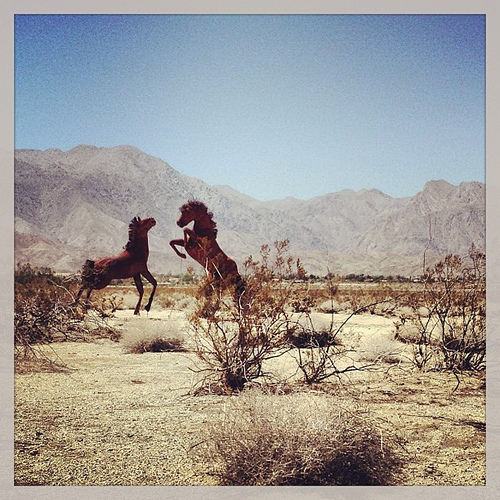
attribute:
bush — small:
[182, 382, 399, 495]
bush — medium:
[185, 243, 335, 398]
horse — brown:
[155, 198, 260, 314]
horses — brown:
[76, 214, 160, 314]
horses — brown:
[175, 197, 251, 311]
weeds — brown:
[299, 327, 479, 472]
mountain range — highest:
[66, 142, 494, 264]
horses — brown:
[87, 204, 249, 322]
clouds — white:
[116, 53, 193, 103]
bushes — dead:
[181, 243, 390, 405]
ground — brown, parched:
[18, 272, 483, 482]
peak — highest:
[73, 142, 140, 154]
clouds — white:
[168, 55, 241, 112]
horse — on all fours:
[55, 201, 176, 338]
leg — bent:
[171, 239, 192, 262]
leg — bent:
[179, 225, 196, 242]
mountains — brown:
[16, 140, 486, 276]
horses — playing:
[74, 199, 249, 317]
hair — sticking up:
[120, 216, 137, 253]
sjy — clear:
[66, 40, 498, 163]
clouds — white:
[376, 97, 439, 142]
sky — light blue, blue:
[16, 19, 480, 201]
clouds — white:
[208, 134, 294, 172]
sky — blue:
[177, 22, 377, 201]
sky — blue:
[126, 20, 436, 146]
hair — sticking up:
[181, 198, 220, 232]